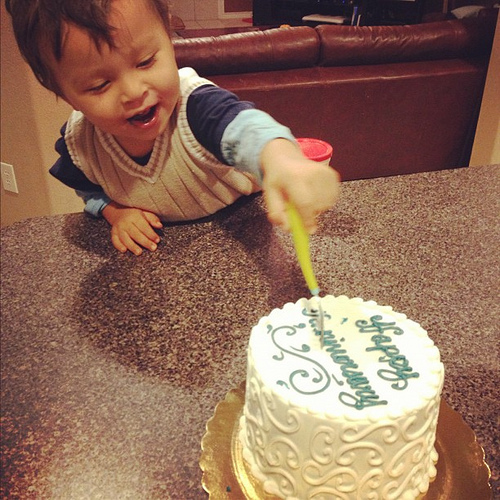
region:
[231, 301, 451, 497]
WHITE LACE ANNIVERSARY CAKE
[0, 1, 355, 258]
BOY IN VEST AND SWEATER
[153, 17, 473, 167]
A BROWN LEATHER COUCH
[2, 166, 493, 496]
MARBLE BLACK AND WHITE TABLE TOP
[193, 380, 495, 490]
GOLD COLORED CAKE PLATE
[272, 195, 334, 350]
YELLOW PLASTIC SPOON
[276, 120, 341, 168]
PLASTIC RED CUP LID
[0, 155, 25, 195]
WHITE RECTANGLE ELECTRIC SOCKET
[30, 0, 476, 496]
BOY TOUCHING CAKE WITH YELLOW SPOON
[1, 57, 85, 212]
BROWN CORNER WALL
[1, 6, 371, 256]
A little boy with a sweater vest on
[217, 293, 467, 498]
White cake with blueish writing on top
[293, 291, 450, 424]
Cake says Happy Anniversary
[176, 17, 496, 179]
A brown leather couch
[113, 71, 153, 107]
A small nose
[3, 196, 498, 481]
A large speckled counter top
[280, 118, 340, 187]
A cup with a red lid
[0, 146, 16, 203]
Electrical outlet on wall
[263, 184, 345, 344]
Something yellow being held by a child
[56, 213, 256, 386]
Shadow on the counter top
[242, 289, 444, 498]
decorated iced cake on tray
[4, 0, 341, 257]
child cutting a cake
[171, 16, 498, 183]
brown leather couch with cushions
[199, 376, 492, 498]
gold tray holding decorated cake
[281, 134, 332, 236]
white and red cup on a table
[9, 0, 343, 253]
little boy leaning on a table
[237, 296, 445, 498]
iced cake with writing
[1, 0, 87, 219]
wall with white electrical outlet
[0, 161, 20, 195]
white electrical outlet on wall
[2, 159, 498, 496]
table with anniversary cake on it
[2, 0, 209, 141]
Young child.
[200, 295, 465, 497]
White cake for an anniversary.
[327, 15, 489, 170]
Brown leather sofa.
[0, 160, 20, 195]
White wall Socket.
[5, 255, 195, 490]
Hard granite countertop.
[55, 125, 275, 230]
Tan and white sweater vest.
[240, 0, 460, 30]
Entertainment center with shelves.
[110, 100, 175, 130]
A small child's smile.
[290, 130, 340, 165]
A sippy cup with a red lid.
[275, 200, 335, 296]
A bright yellow handle.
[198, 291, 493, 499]
Anniversary cake on gold plate.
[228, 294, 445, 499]
Cake iced in white with blue lettering.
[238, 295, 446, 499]
Cake that says Happy Anniversary.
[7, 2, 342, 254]
Little boy.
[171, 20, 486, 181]
Leather sofa.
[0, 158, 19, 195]
Electrical outlet.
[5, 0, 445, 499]
Little boy poking at a cake.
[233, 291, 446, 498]
Cake iced with swirls.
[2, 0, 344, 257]
Little boy in a sweater vest.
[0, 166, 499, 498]
Counter top with an Anniversary cake on it.